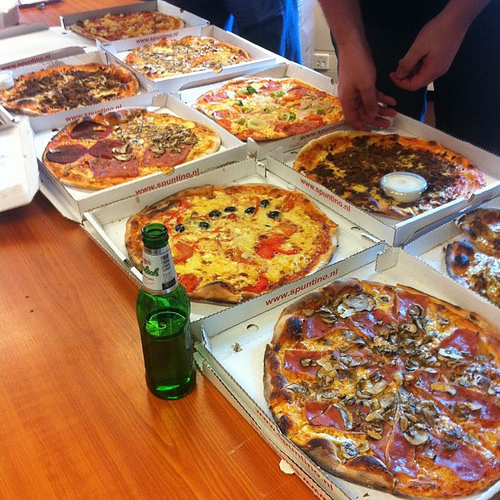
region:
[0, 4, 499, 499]
Open pizza boxes on the table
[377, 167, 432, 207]
Container of blue cheese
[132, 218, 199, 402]
Green open beer bottle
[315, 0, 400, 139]
Right hand of person getting pizza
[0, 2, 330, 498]
Wooden table under the pizza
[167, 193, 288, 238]
Black olives on the pizza next to the beer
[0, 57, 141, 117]
Sausage pizza on the top left of the table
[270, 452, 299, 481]
White tap on the pizza box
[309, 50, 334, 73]
Outlet on the wall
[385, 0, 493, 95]
Right hand of the man getting pizza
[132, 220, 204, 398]
Green bottle on the table.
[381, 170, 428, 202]
White cup on the pizza.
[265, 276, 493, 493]
Mushroom and pepperoni pizza.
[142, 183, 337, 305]
Pepperoni, cheese, and black olive pizza.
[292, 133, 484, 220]
Sausage and cheese pizza.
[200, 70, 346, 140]
Pepperoni, onion, and bell pepper pizza.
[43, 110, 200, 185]
Ham, pepperoni, and mushroom pizza.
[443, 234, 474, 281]
Burnt crust on the pizza.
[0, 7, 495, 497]
Nine pizzas on the table.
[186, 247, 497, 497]
White pizza box under the pizza.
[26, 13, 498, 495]
nine boxes of pizza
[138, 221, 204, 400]
a green beer bottle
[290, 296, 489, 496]
mushroom and ham toppings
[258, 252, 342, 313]
a web address on the pizza box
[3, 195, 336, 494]
a beer bottle on a wooden table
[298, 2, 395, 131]
a hand grabbing a slice of pizza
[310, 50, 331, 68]
a white electrical outlet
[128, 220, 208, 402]
a beer bottle that is half full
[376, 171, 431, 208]
a container of dipping sauce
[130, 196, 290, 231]
black toppings on half of the pizza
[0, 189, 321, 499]
a light brown wooden table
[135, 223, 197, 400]
a green beer bottle on the table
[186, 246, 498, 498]
pizza in a box on the table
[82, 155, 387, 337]
pizza in a box on the table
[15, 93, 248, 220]
pizza in a box on the table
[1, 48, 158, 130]
pizza in a box on the table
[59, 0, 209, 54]
pizza in a box on the table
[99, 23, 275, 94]
pizza in a box on the table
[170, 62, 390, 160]
pizza in a box on the table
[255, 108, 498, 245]
pizza in a box on the table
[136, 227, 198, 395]
a bottle of beer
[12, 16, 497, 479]
eight different pizzas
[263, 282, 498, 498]
a pepperoni and mushroom pizza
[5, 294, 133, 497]
a brown wooden table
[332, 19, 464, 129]
the two hands of a person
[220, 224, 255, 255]
melted white cheese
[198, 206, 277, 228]
some black olives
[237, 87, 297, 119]
some green pepper pieces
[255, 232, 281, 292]
looks like pieces of tomato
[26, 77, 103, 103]
pieces of sausage